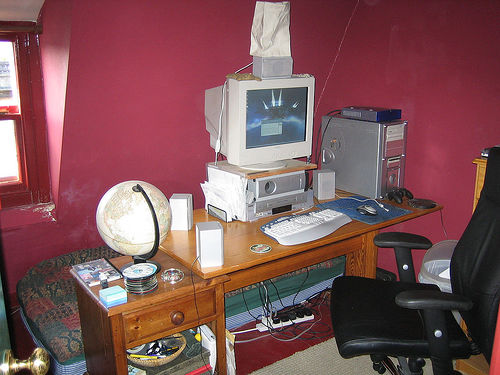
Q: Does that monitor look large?
A: Yes, the monitor is large.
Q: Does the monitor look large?
A: Yes, the monitor is large.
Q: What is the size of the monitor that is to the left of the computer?
A: The monitor is large.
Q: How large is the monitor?
A: The monitor is large.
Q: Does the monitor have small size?
A: No, the monitor is large.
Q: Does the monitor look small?
A: No, the monitor is large.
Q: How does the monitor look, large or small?
A: The monitor is large.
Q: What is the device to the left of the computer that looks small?
A: The device is a monitor.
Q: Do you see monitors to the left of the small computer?
A: Yes, there is a monitor to the left of the computer.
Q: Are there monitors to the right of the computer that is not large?
A: No, the monitor is to the left of the computer.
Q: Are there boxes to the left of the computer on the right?
A: No, there is a monitor to the left of the computer.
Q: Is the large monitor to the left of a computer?
A: Yes, the monitor is to the left of a computer.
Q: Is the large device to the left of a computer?
A: Yes, the monitor is to the left of a computer.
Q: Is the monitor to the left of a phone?
A: No, the monitor is to the left of a computer.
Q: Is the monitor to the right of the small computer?
A: No, the monitor is to the left of the computer.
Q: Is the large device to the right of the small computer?
A: No, the monitor is to the left of the computer.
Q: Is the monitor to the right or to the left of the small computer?
A: The monitor is to the left of the computer.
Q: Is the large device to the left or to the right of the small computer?
A: The monitor is to the left of the computer.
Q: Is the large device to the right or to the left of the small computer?
A: The monitor is to the left of the computer.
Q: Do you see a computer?
A: Yes, there is a computer.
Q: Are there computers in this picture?
A: Yes, there is a computer.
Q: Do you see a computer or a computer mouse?
A: Yes, there is a computer.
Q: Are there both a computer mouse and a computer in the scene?
A: Yes, there are both a computer and a computer mouse.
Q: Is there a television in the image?
A: No, there are no televisions.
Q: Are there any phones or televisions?
A: No, there are no televisions or phones.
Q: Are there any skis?
A: No, there are no skis.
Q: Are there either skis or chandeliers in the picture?
A: No, there are no skis or chandeliers.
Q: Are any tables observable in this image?
A: Yes, there is a table.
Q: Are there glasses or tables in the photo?
A: Yes, there is a table.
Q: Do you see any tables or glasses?
A: Yes, there is a table.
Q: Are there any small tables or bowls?
A: Yes, there is a small table.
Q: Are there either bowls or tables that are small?
A: Yes, the table is small.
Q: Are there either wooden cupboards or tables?
A: Yes, there is a wood table.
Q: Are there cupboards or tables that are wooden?
A: Yes, the table is wooden.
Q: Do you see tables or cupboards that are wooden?
A: Yes, the table is wooden.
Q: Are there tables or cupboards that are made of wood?
A: Yes, the table is made of wood.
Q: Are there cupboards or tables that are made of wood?
A: Yes, the table is made of wood.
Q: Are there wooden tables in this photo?
A: Yes, there is a wood table.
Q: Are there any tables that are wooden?
A: Yes, there is a table that is wooden.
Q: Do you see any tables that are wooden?
A: Yes, there is a table that is wooden.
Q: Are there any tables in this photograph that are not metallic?
A: Yes, there is a wooden table.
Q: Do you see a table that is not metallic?
A: Yes, there is a wooden table.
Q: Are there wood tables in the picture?
A: Yes, there is a table that is made of wood.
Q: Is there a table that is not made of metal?
A: Yes, there is a table that is made of wood.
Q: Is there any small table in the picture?
A: Yes, there is a small table.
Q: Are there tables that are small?
A: Yes, there is a table that is small.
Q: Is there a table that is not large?
A: Yes, there is a small table.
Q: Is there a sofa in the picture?
A: No, there are no sofas.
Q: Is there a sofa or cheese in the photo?
A: No, there are no sofas or cheese.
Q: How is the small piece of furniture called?
A: The piece of furniture is a table.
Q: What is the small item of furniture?
A: The piece of furniture is a table.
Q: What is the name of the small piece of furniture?
A: The piece of furniture is a table.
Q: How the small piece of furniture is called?
A: The piece of furniture is a table.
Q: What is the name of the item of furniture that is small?
A: The piece of furniture is a table.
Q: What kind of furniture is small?
A: The furniture is a table.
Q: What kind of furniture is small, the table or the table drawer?
A: The table is small.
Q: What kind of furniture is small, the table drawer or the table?
A: The table is small.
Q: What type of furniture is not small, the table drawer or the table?
A: The drawer is not small.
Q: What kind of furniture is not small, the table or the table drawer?
A: The drawer is not small.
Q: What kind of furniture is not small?
A: The furniture is a drawer.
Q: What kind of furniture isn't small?
A: The furniture is a drawer.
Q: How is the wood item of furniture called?
A: The piece of furniture is a table.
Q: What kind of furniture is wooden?
A: The furniture is a table.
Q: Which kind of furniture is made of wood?
A: The furniture is a table.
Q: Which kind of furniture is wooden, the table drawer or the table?
A: The table is wooden.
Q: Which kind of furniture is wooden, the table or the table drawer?
A: The table is wooden.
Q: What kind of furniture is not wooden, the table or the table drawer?
A: The drawer is not wooden.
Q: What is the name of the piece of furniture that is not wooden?
A: The piece of furniture is a drawer.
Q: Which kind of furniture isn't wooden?
A: The furniture is a drawer.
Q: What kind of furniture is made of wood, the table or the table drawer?
A: The table is made of wood.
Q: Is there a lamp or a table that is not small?
A: No, there is a table but it is small.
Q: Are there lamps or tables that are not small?
A: No, there is a table but it is small.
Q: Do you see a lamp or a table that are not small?
A: No, there is a table but it is small.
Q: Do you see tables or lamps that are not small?
A: No, there is a table but it is small.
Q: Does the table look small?
A: Yes, the table is small.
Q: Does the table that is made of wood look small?
A: Yes, the table is small.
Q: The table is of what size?
A: The table is small.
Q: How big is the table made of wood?
A: The table is small.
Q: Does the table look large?
A: No, the table is small.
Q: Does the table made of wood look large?
A: No, the table is small.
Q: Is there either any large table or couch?
A: No, there is a table but it is small.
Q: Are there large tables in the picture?
A: No, there is a table but it is small.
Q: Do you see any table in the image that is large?
A: No, there is a table but it is small.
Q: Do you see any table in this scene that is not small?
A: No, there is a table but it is small.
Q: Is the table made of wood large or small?
A: The table is small.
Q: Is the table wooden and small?
A: Yes, the table is wooden and small.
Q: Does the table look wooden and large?
A: No, the table is wooden but small.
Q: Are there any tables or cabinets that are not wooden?
A: No, there is a table but it is wooden.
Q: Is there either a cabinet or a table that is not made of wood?
A: No, there is a table but it is made of wood.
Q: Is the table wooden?
A: Yes, the table is wooden.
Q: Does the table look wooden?
A: Yes, the table is wooden.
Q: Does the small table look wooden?
A: Yes, the table is wooden.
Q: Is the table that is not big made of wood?
A: Yes, the table is made of wood.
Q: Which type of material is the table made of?
A: The table is made of wood.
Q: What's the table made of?
A: The table is made of wood.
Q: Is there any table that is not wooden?
A: No, there is a table but it is wooden.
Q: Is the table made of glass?
A: No, the table is made of wood.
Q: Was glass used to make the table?
A: No, the table is made of wood.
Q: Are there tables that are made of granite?
A: No, there is a table but it is made of wood.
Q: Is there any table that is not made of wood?
A: No, there is a table but it is made of wood.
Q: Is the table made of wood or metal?
A: The table is made of wood.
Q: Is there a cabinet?
A: No, there are no cabinets.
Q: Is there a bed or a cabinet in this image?
A: No, there are no cabinets or beds.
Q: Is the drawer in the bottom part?
A: Yes, the drawer is in the bottom of the image.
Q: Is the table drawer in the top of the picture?
A: No, the drawer is in the bottom of the image.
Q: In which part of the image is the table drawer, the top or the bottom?
A: The drawer is in the bottom of the image.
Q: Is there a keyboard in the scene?
A: Yes, there is a keyboard.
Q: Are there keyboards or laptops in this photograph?
A: Yes, there is a keyboard.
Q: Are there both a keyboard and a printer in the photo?
A: No, there is a keyboard but no printers.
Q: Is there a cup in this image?
A: No, there are no cups.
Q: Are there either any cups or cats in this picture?
A: No, there are no cups or cats.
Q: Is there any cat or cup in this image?
A: No, there are no cups or cats.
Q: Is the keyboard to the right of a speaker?
A: Yes, the keyboard is to the right of a speaker.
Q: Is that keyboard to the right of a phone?
A: No, the keyboard is to the right of a speaker.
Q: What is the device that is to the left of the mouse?
A: The device is a keyboard.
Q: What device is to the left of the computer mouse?
A: The device is a keyboard.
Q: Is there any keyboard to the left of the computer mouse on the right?
A: Yes, there is a keyboard to the left of the mouse.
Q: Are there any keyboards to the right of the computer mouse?
A: No, the keyboard is to the left of the computer mouse.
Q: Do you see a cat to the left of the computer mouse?
A: No, there is a keyboard to the left of the computer mouse.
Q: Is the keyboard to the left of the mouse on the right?
A: Yes, the keyboard is to the left of the mouse.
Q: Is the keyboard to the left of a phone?
A: No, the keyboard is to the left of the mouse.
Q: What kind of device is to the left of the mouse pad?
A: The device is a keyboard.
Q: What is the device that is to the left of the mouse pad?
A: The device is a keyboard.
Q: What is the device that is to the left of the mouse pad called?
A: The device is a keyboard.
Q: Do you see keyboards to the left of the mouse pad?
A: Yes, there is a keyboard to the left of the mouse pad.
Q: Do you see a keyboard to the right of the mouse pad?
A: No, the keyboard is to the left of the mouse pad.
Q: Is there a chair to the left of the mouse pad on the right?
A: No, there is a keyboard to the left of the mousepad.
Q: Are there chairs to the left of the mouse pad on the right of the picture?
A: No, there is a keyboard to the left of the mousepad.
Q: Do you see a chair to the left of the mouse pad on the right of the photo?
A: No, there is a keyboard to the left of the mousepad.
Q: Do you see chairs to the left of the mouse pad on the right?
A: No, there is a keyboard to the left of the mousepad.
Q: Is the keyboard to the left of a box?
A: No, the keyboard is to the left of a mouse pad.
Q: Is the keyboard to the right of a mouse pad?
A: No, the keyboard is to the left of a mouse pad.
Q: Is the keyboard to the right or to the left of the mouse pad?
A: The keyboard is to the left of the mouse pad.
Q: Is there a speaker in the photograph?
A: Yes, there is a speaker.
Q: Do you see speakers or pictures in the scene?
A: Yes, there is a speaker.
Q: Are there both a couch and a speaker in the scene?
A: No, there is a speaker but no couches.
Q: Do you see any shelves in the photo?
A: No, there are no shelves.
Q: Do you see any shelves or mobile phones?
A: No, there are no shelves or mobile phones.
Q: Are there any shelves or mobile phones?
A: No, there are no shelves or mobile phones.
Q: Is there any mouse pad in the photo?
A: Yes, there is a mouse pad.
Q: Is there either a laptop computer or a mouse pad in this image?
A: Yes, there is a mouse pad.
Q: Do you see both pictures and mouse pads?
A: No, there is a mouse pad but no pictures.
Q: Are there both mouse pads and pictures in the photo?
A: No, there is a mouse pad but no pictures.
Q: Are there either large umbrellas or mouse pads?
A: Yes, there is a large mouse pad.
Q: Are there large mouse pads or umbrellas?
A: Yes, there is a large mouse pad.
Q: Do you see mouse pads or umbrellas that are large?
A: Yes, the mouse pad is large.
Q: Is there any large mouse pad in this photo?
A: Yes, there is a large mouse pad.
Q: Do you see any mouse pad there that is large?
A: Yes, there is a mouse pad that is large.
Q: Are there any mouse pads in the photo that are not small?
A: Yes, there is a large mouse pad.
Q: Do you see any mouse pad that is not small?
A: Yes, there is a large mouse pad.